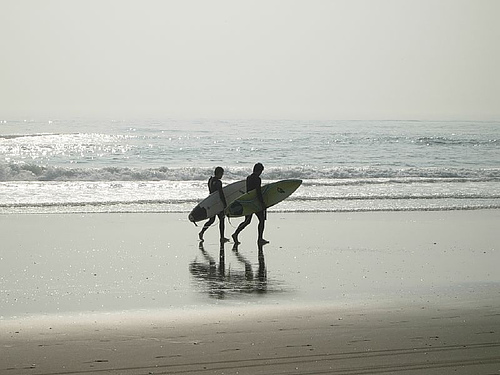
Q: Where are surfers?
A: On the beach.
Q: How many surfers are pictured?
A: Two.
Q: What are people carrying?
A: Surfboards.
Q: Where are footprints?
A: On the sand.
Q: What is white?
A: Surfboards.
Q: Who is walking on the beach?
A: Two men.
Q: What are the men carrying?
A: Surfboards.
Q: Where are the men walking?
A: On the beach.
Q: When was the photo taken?
A: Daytime.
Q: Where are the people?
A: On the beach.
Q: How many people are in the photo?
A: Two.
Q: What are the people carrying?
A: Surfboards.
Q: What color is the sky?
A: Grey.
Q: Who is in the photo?
A: Two men.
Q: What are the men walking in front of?
A: The ocean.